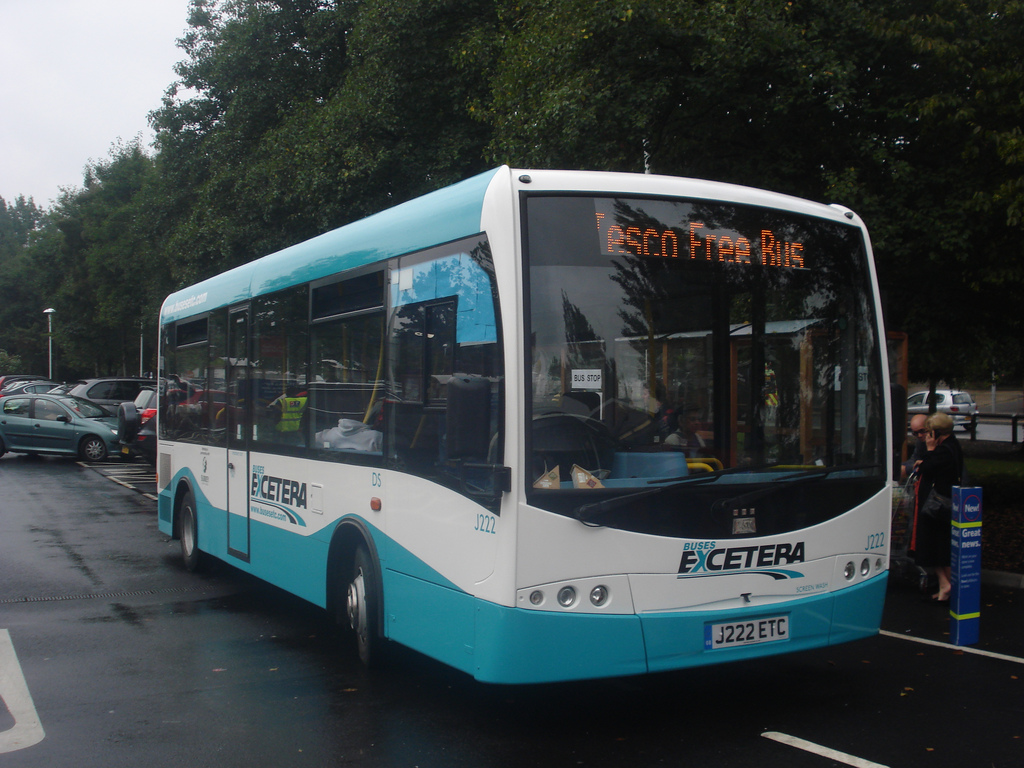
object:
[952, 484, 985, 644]
pole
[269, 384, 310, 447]
person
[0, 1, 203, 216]
sky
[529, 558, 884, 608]
bus lights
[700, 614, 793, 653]
plate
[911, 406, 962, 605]
people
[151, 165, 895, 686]
bus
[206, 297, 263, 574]
door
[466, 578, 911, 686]
bumper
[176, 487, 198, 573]
tire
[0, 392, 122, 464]
car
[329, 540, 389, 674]
front tire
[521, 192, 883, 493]
windshield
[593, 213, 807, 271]
letters